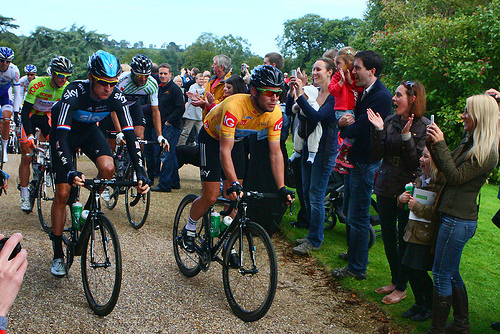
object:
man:
[182, 65, 295, 269]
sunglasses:
[255, 87, 283, 96]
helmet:
[249, 64, 284, 87]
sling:
[297, 114, 318, 139]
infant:
[287, 85, 322, 165]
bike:
[172, 186, 293, 322]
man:
[116, 55, 171, 157]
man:
[330, 51, 391, 281]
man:
[187, 54, 232, 120]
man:
[151, 62, 185, 192]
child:
[327, 47, 364, 174]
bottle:
[210, 210, 220, 238]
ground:
[0, 154, 499, 334]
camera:
[0, 237, 21, 260]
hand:
[0, 230, 27, 319]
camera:
[291, 69, 297, 76]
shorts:
[197, 125, 244, 181]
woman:
[285, 58, 338, 255]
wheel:
[223, 221, 278, 323]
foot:
[181, 225, 196, 253]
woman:
[425, 95, 499, 334]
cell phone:
[431, 115, 435, 124]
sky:
[0, 0, 375, 62]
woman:
[368, 82, 432, 304]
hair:
[402, 81, 426, 118]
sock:
[51, 233, 63, 258]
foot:
[50, 258, 66, 277]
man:
[52, 49, 152, 276]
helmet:
[86, 50, 121, 78]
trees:
[372, 15, 499, 133]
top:
[24, 77, 70, 116]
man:
[13, 56, 74, 212]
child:
[397, 146, 442, 320]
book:
[408, 188, 437, 223]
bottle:
[405, 181, 413, 210]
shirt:
[328, 71, 363, 110]